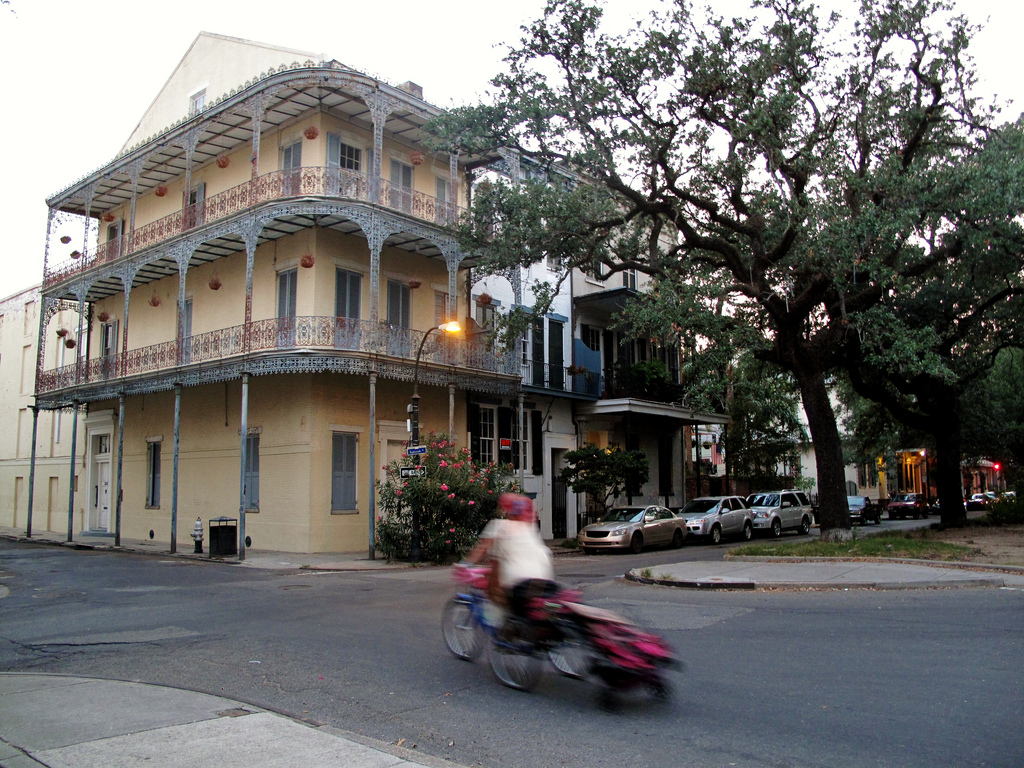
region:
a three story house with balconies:
[21, 26, 524, 565]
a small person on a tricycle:
[433, 493, 696, 719]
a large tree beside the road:
[387, 0, 1020, 557]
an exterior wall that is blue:
[570, 312, 688, 411]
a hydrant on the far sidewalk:
[181, 508, 213, 559]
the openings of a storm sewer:
[610, 571, 760, 594]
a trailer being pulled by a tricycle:
[577, 617, 679, 715]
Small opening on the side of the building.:
[204, 508, 256, 569]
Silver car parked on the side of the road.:
[584, 484, 679, 561]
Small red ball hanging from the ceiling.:
[194, 240, 237, 294]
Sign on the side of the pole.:
[397, 434, 433, 461]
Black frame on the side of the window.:
[459, 400, 498, 465]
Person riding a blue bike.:
[439, 555, 547, 691]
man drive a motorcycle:
[423, 470, 717, 734]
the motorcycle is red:
[428, 552, 688, 723]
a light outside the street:
[392, 298, 476, 423]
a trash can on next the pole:
[201, 511, 249, 566]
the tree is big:
[454, 0, 932, 538]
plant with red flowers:
[372, 423, 494, 566]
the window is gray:
[324, 425, 367, 523]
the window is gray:
[230, 416, 270, 518]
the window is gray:
[326, 257, 371, 344]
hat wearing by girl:
[496, 470, 550, 543]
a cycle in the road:
[345, 467, 827, 746]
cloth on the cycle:
[436, 535, 510, 615]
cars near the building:
[580, 468, 923, 571]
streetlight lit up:
[403, 308, 464, 562]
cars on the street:
[580, 481, 811, 555]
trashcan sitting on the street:
[200, 510, 243, 569]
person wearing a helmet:
[464, 477, 557, 614]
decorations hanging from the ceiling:
[53, 221, 91, 266]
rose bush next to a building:
[366, 431, 500, 569]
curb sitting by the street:
[622, 550, 1005, 599]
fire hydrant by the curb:
[184, 513, 208, 555]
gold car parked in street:
[574, 497, 685, 552]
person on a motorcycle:
[437, 487, 691, 715]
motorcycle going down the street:
[1, 489, 1019, 766]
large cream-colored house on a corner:
[30, 26, 502, 561]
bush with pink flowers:
[368, 432, 505, 570]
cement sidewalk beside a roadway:
[2, 673, 435, 766]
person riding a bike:
[441, 490, 686, 718]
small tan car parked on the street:
[574, 500, 691, 551]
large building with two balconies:
[48, 28, 513, 564]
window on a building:
[135, 436, 168, 513]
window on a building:
[318, 414, 370, 519]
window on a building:
[160, 281, 206, 376]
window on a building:
[255, 255, 319, 351]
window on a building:
[322, 256, 365, 345]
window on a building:
[379, 268, 424, 360]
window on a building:
[256, 129, 308, 196]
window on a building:
[331, 126, 382, 202]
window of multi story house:
[101, 220, 128, 262]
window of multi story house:
[185, 192, 195, 219]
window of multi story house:
[279, 144, 302, 199]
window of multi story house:
[338, 141, 362, 193]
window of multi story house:
[386, 149, 412, 211]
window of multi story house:
[434, 177, 461, 220]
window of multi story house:
[434, 291, 458, 348]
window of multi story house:
[389, 278, 408, 351]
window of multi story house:
[335, 266, 361, 353]